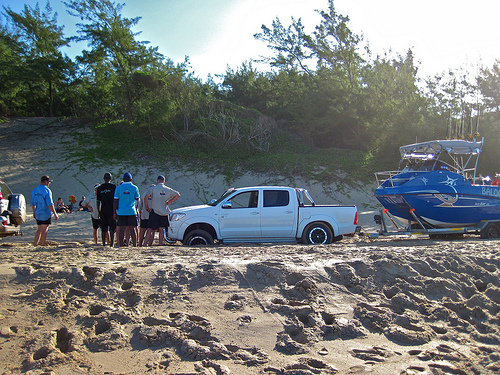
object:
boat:
[370, 136, 500, 243]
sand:
[0, 250, 499, 375]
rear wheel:
[302, 220, 335, 246]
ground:
[0, 234, 499, 374]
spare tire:
[7, 192, 29, 226]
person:
[94, 171, 117, 246]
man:
[112, 172, 140, 249]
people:
[143, 175, 181, 244]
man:
[28, 175, 61, 247]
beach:
[0, 217, 499, 375]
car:
[0, 181, 27, 237]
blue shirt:
[112, 180, 141, 216]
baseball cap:
[122, 171, 132, 183]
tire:
[302, 222, 332, 245]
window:
[262, 189, 289, 206]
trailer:
[380, 207, 499, 240]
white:
[166, 182, 358, 246]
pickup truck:
[168, 184, 358, 245]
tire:
[183, 228, 213, 245]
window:
[230, 189, 259, 209]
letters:
[481, 186, 500, 199]